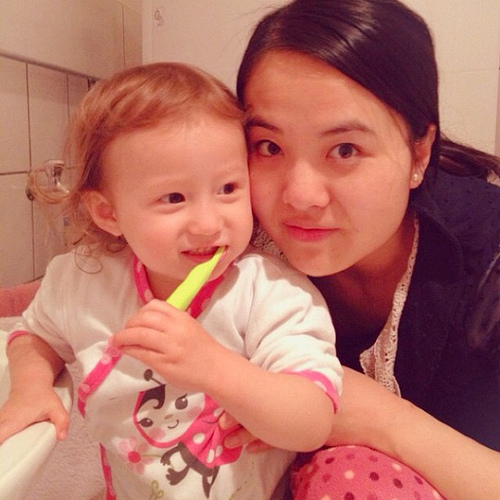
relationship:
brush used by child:
[166, 247, 226, 313] [0, 60, 341, 497]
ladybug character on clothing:
[132, 364, 266, 496] [3, 239, 345, 499]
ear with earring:
[409, 124, 438, 189] [409, 171, 423, 183]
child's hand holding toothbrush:
[106, 295, 219, 391] [164, 244, 229, 313]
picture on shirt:
[127, 359, 268, 493] [17, 228, 350, 498]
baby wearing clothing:
[0, 64, 342, 500] [2, 242, 343, 498]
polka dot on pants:
[367, 455, 378, 462] [289, 445, 448, 499]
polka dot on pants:
[343, 470, 355, 480] [289, 445, 448, 499]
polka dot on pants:
[325, 455, 335, 464] [289, 445, 448, 499]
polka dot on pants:
[414, 475, 425, 485] [289, 445, 448, 499]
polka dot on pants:
[346, 452, 357, 459] [289, 445, 448, 499]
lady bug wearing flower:
[134, 368, 253, 497] [116, 434, 155, 475]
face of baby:
[109, 109, 254, 282] [0, 64, 342, 500]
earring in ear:
[410, 170, 420, 184] [409, 124, 438, 189]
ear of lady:
[409, 124, 438, 189] [237, 1, 500, 500]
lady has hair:
[237, 1, 497, 498] [235, 1, 499, 175]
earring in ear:
[412, 172, 420, 182] [408, 124, 438, 186]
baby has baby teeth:
[0, 64, 342, 500] [188, 246, 213, 256]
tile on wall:
[66, 73, 93, 168] [6, 1, 142, 285]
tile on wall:
[23, 62, 77, 171] [6, 1, 142, 285]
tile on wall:
[1, 52, 35, 177] [6, 1, 142, 285]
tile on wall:
[29, 164, 69, 282] [6, 1, 142, 285]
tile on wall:
[0, 168, 37, 293] [6, 1, 142, 285]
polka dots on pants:
[390, 461, 403, 472] [293, 443, 442, 498]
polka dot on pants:
[343, 470, 355, 480] [293, 443, 442, 498]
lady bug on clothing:
[134, 367, 253, 496] [2, 242, 343, 498]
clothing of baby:
[2, 242, 343, 498] [3, 61, 341, 497]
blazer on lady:
[389, 170, 496, 453] [237, 1, 500, 500]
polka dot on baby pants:
[330, 454, 383, 499] [292, 437, 431, 499]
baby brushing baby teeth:
[0, 64, 342, 500] [197, 248, 210, 253]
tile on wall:
[0, 172, 34, 288] [0, 61, 74, 278]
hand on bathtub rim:
[2, 331, 73, 445] [2, 316, 75, 497]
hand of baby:
[2, 331, 73, 445] [0, 64, 342, 500]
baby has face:
[56, 74, 332, 495] [109, 109, 254, 282]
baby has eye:
[0, 64, 342, 500] [218, 182, 239, 196]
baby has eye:
[0, 64, 342, 500] [155, 191, 185, 207]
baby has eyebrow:
[0, 64, 342, 500] [213, 164, 247, 180]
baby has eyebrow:
[0, 64, 342, 500] [135, 178, 182, 203]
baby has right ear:
[0, 64, 342, 500] [76, 185, 127, 243]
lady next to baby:
[237, 1, 500, 500] [3, 61, 341, 497]